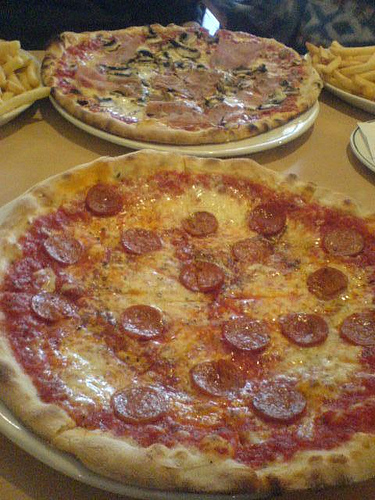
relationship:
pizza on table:
[0, 148, 374, 498] [1, 37, 374, 499]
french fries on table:
[304, 34, 374, 116] [1, 37, 374, 499]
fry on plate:
[1, 85, 54, 114] [2, 102, 40, 125]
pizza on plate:
[0, 148, 374, 498] [0, 406, 245, 500]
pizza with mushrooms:
[43, 14, 325, 145] [174, 38, 206, 60]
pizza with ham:
[43, 14, 325, 145] [204, 40, 252, 68]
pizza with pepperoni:
[0, 148, 374, 498] [247, 201, 287, 239]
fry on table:
[1, 85, 54, 114] [1, 37, 374, 499]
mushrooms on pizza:
[174, 38, 206, 60] [0, 148, 374, 498]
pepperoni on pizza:
[247, 201, 287, 239] [0, 148, 374, 498]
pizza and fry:
[0, 148, 374, 498] [1, 85, 54, 114]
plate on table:
[2, 102, 40, 125] [1, 37, 374, 499]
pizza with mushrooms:
[0, 148, 374, 498] [174, 38, 206, 60]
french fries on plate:
[304, 34, 374, 116] [2, 102, 40, 125]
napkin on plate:
[358, 118, 374, 161] [2, 102, 40, 125]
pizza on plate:
[0, 148, 374, 498] [2, 102, 40, 125]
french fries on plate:
[304, 34, 374, 116] [314, 66, 374, 117]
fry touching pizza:
[1, 83, 54, 120] [43, 14, 325, 145]